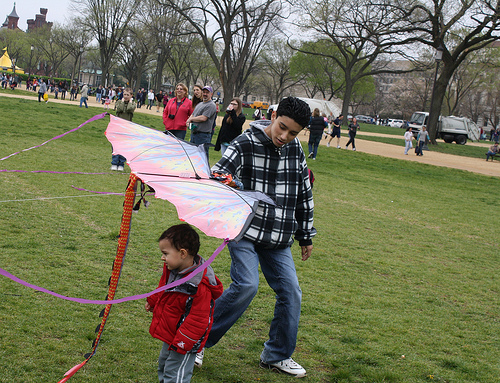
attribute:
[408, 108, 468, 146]
truck — white, behind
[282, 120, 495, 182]
path — walking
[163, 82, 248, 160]
people — group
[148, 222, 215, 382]
man — young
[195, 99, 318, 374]
man — young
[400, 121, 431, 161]
couple — walking, talking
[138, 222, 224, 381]
little boy — wearing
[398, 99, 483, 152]
truck — white, behind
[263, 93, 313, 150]
hair — black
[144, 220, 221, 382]
boy — young, wearing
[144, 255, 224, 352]
boy — young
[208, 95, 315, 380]
man — holding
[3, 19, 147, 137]
hill — brown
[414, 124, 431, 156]
person — walking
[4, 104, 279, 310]
kite — pink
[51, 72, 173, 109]
people — watching off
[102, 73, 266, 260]
people kites —  people's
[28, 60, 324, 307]
kite — hanging off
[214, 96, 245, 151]
lady — wearing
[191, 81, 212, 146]
people — standing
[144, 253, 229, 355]
jacket — red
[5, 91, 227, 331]
tails — purple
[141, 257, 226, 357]
coat — red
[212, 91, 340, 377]
man — young